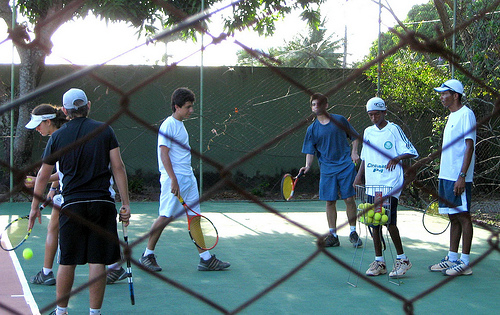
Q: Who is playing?
A: The boys.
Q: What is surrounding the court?
A: Fence.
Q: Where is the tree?
A: Next to court.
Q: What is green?
A: Court.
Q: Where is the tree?
A: Behind the fence.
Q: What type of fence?
A: Chain link.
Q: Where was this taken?
A: Tennis court.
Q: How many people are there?
A: 6.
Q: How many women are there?
A: 1.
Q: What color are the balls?
A: Yellow.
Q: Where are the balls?
A: In the basket.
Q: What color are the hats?
A: White.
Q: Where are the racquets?
A: In the people's hands.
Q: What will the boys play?
A: Tennis.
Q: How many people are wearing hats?
A: Four.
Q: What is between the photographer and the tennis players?
A: A fence.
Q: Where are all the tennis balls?
A: In a wire basket.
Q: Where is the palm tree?
A: Behind to court and fence.